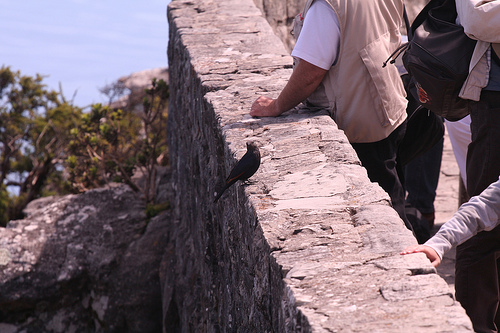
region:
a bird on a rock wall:
[214, 110, 272, 217]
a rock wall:
[115, 10, 362, 331]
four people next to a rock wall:
[279, 31, 485, 282]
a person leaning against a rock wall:
[240, 6, 347, 126]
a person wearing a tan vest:
[326, 5, 367, 100]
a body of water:
[33, 11, 139, 73]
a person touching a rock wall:
[386, 220, 473, 276]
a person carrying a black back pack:
[408, 9, 474, 131]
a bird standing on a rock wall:
[208, 135, 270, 212]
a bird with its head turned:
[240, 135, 258, 157]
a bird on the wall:
[159, 126, 269, 198]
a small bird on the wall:
[172, 103, 300, 238]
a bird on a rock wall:
[142, 131, 372, 321]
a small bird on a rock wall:
[139, 108, 354, 245]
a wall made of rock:
[144, 86, 341, 325]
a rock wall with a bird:
[143, 119, 403, 327]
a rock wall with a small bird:
[96, 92, 410, 328]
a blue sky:
[40, 17, 149, 77]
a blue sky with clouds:
[32, 8, 150, 65]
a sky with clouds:
[37, 31, 238, 142]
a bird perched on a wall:
[201, 137, 270, 204]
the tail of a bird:
[208, 178, 233, 205]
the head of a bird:
[243, 135, 264, 156]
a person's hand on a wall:
[392, 228, 440, 268]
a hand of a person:
[243, 88, 285, 123]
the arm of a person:
[419, 183, 498, 272]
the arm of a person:
[265, 13, 342, 124]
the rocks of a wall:
[250, 199, 429, 309]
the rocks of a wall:
[169, 69, 213, 194]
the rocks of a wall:
[173, 9, 279, 73]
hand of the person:
[233, 88, 282, 121]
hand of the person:
[378, 235, 444, 262]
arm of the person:
[278, 66, 323, 101]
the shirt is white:
[296, 10, 337, 52]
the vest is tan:
[355, 31, 398, 81]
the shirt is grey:
[422, 215, 475, 246]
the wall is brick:
[277, 185, 340, 235]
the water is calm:
[40, 26, 85, 58]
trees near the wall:
[25, 90, 120, 156]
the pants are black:
[356, 137, 412, 169]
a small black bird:
[211, 137, 261, 200]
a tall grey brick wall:
[165, 0, 471, 332]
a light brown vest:
[314, 1, 408, 143]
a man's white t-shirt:
[292, 2, 340, 69]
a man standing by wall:
[251, 1, 407, 211]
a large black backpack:
[404, 1, 479, 123]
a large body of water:
[0, 2, 172, 105]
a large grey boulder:
[0, 179, 139, 331]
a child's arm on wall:
[397, 184, 497, 266]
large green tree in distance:
[0, 64, 82, 223]